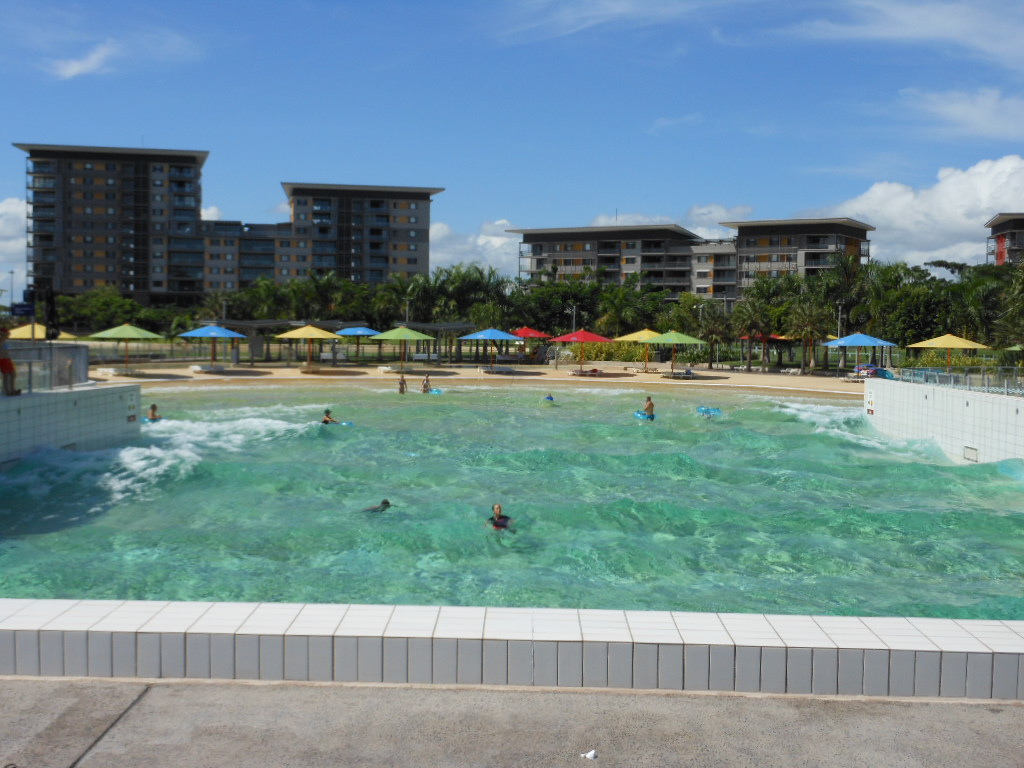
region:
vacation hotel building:
[19, 130, 1016, 309]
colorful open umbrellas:
[72, 299, 967, 391]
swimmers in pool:
[212, 392, 925, 612]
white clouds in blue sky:
[113, 40, 159, 83]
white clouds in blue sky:
[170, 29, 235, 75]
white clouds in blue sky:
[889, 171, 953, 226]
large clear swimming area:
[0, 376, 1021, 612]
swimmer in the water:
[483, 499, 526, 542]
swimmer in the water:
[352, 496, 400, 522]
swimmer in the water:
[309, 402, 348, 437]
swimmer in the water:
[640, 383, 664, 425]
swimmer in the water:
[539, 390, 566, 417]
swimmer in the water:
[309, 396, 347, 434]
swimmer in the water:
[134, 398, 172, 425]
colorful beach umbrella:
[461, 316, 523, 367]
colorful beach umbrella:
[650, 325, 704, 370]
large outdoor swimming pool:
[0, 376, 1022, 694]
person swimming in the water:
[486, 502, 518, 540]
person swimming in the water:
[360, 496, 393, 519]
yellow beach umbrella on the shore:
[278, 322, 337, 371]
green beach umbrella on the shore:
[367, 325, 434, 371]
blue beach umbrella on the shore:
[457, 326, 518, 366]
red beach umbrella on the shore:
[547, 326, 609, 374]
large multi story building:
[13, 137, 443, 296]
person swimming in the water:
[318, 407, 347, 428]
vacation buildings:
[49, 151, 903, 322]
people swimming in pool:
[128, 362, 825, 607]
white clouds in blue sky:
[66, 28, 128, 77]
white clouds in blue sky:
[208, 39, 285, 74]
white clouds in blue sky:
[277, 112, 354, 148]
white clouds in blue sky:
[465, 55, 548, 104]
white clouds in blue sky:
[811, 33, 882, 72]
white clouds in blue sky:
[907, 87, 985, 144]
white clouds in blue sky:
[885, 178, 975, 232]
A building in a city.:
[982, 213, 1018, 271]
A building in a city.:
[10, 137, 437, 300]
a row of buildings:
[33, 131, 951, 310]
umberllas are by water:
[0, 305, 976, 417]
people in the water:
[256, 365, 686, 562]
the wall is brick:
[352, 602, 755, 713]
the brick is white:
[453, 599, 663, 679]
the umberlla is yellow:
[908, 318, 989, 360]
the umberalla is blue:
[801, 324, 896, 357]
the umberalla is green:
[646, 315, 708, 355]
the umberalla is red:
[554, 321, 600, 345]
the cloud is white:
[928, 155, 1012, 213]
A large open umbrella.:
[381, 329, 426, 362]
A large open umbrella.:
[337, 323, 383, 344]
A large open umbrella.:
[281, 327, 343, 347]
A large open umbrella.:
[182, 320, 241, 343]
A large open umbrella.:
[87, 321, 170, 340]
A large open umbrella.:
[8, 324, 85, 347]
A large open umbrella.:
[464, 326, 519, 345]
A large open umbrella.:
[503, 320, 562, 341]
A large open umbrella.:
[546, 327, 601, 341]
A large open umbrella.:
[610, 324, 659, 343]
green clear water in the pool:
[25, 380, 1022, 606]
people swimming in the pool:
[152, 373, 678, 567]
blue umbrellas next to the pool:
[185, 314, 903, 371]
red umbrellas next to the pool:
[515, 316, 610, 364]